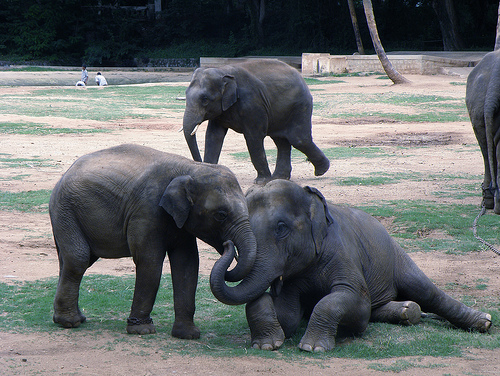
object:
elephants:
[464, 49, 500, 216]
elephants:
[177, 57, 330, 185]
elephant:
[48, 143, 258, 339]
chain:
[472, 203, 500, 254]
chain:
[463, 47, 498, 214]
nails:
[260, 343, 273, 351]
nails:
[300, 343, 312, 352]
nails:
[400, 307, 409, 319]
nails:
[485, 314, 492, 322]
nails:
[140, 327, 151, 334]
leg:
[397, 257, 493, 333]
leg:
[168, 245, 201, 340]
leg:
[126, 222, 164, 336]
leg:
[242, 117, 271, 186]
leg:
[202, 124, 228, 165]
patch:
[317, 115, 474, 150]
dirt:
[2, 315, 492, 375]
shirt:
[95, 75, 108, 86]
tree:
[360, 1, 411, 84]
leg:
[244, 289, 304, 349]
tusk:
[191, 122, 199, 135]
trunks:
[181, 107, 206, 163]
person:
[80, 63, 89, 86]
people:
[94, 71, 108, 85]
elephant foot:
[462, 307, 490, 333]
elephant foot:
[171, 317, 204, 339]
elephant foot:
[310, 155, 331, 176]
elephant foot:
[295, 325, 336, 353]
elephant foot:
[53, 305, 85, 328]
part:
[478, 314, 481, 319]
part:
[308, 335, 312, 345]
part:
[186, 326, 193, 334]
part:
[66, 311, 73, 319]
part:
[321, 162, 325, 167]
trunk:
[363, 0, 410, 84]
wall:
[301, 53, 468, 76]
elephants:
[208, 178, 493, 352]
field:
[0, 64, 499, 376]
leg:
[297, 271, 373, 355]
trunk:
[216, 217, 257, 281]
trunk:
[207, 237, 289, 305]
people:
[75, 80, 86, 86]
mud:
[365, 128, 453, 152]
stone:
[358, 71, 377, 77]